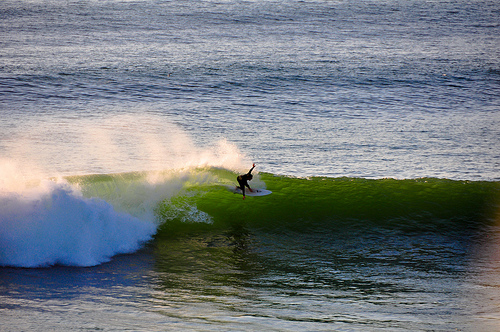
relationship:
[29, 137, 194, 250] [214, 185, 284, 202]
wave with surfboard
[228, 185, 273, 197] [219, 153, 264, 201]
board with wetsuit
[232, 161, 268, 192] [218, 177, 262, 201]
wetsuit with surfboard